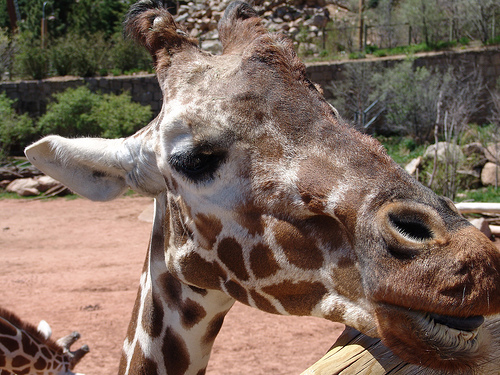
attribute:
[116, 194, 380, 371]
fur — spotted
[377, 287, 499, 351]
mouth — open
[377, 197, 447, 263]
nose — black and brown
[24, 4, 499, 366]
giraffe's head — closeup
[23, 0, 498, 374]
giraffe — v, spottedy, bend down, near camera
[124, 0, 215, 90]
horn — furry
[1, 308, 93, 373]
giraffe — near camera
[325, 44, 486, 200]
trees — skinny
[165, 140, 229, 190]
brown eye — large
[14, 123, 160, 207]
ear — white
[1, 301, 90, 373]
giraffe — grazing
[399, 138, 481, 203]
rocks — stack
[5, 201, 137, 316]
floor — dirt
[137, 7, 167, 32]
tip — black